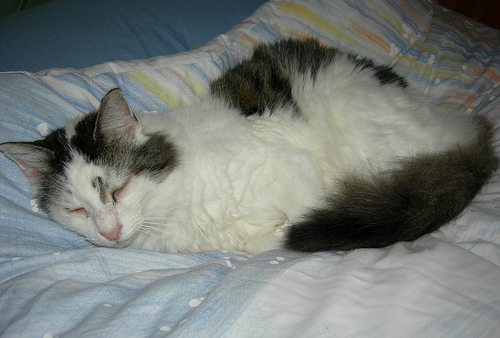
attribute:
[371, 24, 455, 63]
pillow — blue, striped, orange, yellow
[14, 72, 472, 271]
cat — black, white, sleeping, fluffy, napping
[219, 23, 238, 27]
comforter — blue, white, striped, fluffy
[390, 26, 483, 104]
bleach stain — white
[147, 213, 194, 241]
whiskers — white